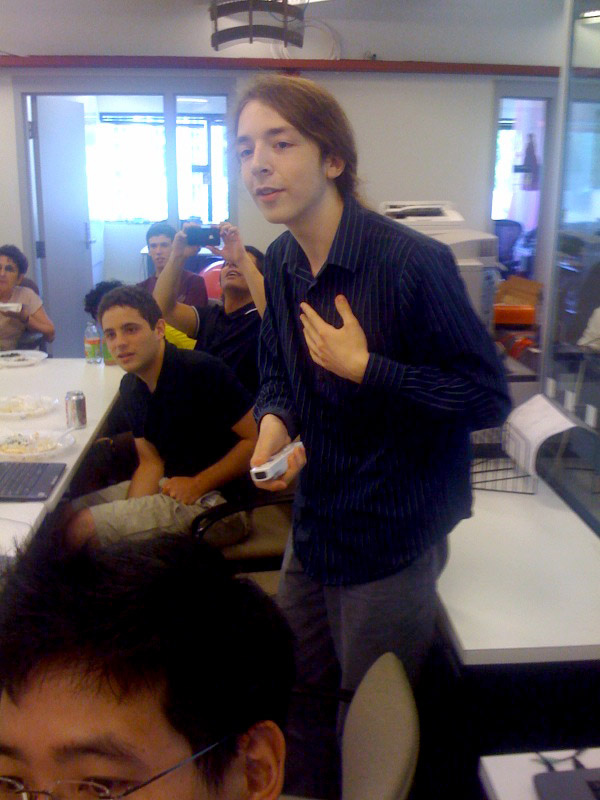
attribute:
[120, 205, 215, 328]
person — sitting down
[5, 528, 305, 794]
person — sitting down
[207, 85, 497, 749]
person — standintg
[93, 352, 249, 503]
clothing — piece 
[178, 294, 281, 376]
clothing — piece 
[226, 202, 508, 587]
clothing — piece 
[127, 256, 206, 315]
clothing — piece 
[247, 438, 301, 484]
controller — white game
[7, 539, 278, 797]
glasses — eye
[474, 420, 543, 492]
wirebasket — black wire 